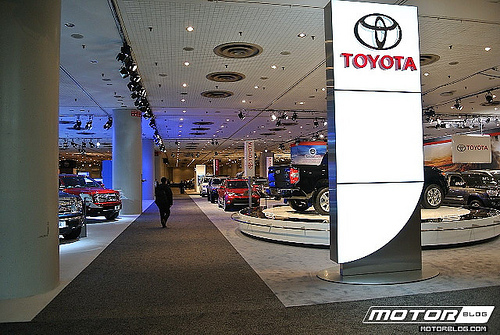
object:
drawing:
[354, 14, 402, 51]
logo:
[340, 13, 417, 72]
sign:
[323, 0, 425, 278]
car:
[218, 178, 262, 212]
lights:
[114, 44, 167, 154]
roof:
[57, 3, 498, 168]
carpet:
[0, 187, 500, 335]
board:
[324, 1, 424, 278]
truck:
[269, 152, 448, 215]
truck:
[0, 28, 61, 292]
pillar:
[110, 108, 141, 215]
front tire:
[423, 184, 445, 209]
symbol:
[353, 13, 402, 51]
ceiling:
[58, 4, 500, 169]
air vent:
[218, 45, 260, 58]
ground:
[447, 158, 482, 184]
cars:
[207, 175, 232, 203]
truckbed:
[268, 152, 329, 189]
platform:
[239, 206, 500, 251]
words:
[340, 52, 417, 71]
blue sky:
[214, 171, 261, 218]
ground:
[390, 113, 418, 128]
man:
[153, 176, 173, 229]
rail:
[239, 204, 500, 232]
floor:
[3, 187, 499, 333]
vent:
[213, 41, 262, 59]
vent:
[206, 72, 245, 82]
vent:
[201, 90, 234, 98]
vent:
[193, 122, 213, 125]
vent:
[191, 128, 207, 135]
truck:
[57, 184, 83, 243]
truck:
[266, 147, 448, 210]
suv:
[206, 175, 232, 203]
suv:
[59, 174, 123, 220]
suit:
[154, 184, 174, 205]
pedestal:
[238, 204, 500, 250]